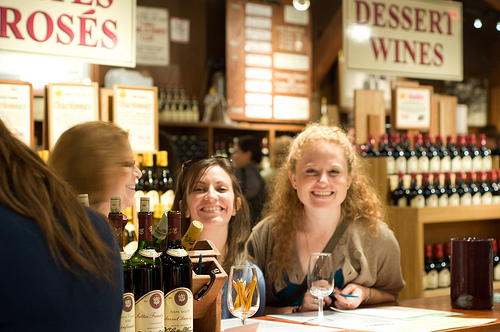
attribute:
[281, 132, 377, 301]
woman — smiling, light skinned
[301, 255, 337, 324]
glass — empty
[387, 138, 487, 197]
bottles — wine, champagne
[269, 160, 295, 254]
hair — long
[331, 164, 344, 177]
eye — open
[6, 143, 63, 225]
hair — brown, long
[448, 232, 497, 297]
vessel — ceramic, brown, large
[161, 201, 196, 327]
bottle — opened, wine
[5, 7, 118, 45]
lettering — red, sign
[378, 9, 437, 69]
letters — red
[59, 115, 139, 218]
woman — turned, smiling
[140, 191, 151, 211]
cork — bottle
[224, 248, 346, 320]
glasses — champagne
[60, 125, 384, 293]
women — happy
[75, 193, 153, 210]
corks — three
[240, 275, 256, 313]
pencils — small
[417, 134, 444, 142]
tops — red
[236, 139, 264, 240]
person — standing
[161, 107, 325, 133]
shelf — wooden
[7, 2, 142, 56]
writings — bold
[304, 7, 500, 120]
area — dessert wine, rose wine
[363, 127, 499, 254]
wines — stacked, displayed